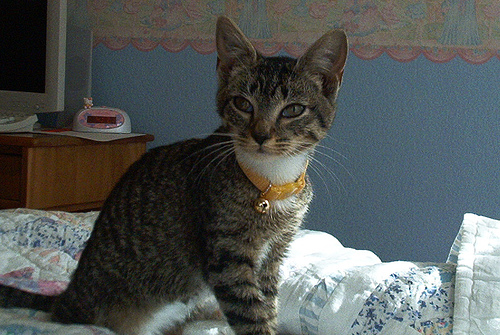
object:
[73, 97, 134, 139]
clock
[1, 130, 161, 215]
table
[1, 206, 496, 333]
comforter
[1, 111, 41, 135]
white keyboard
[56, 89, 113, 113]
figure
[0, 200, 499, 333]
blanket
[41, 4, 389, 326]
cat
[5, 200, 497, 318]
bed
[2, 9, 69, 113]
frame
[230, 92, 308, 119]
eyes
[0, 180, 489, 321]
quilt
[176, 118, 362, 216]
whiskers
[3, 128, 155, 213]
nightstand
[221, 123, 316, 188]
neck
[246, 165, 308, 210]
yellow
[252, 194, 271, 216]
bell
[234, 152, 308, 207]
collar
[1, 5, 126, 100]
computer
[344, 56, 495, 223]
wall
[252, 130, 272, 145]
nose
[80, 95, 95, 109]
hello kitty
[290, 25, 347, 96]
ear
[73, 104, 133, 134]
clock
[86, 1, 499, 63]
picture